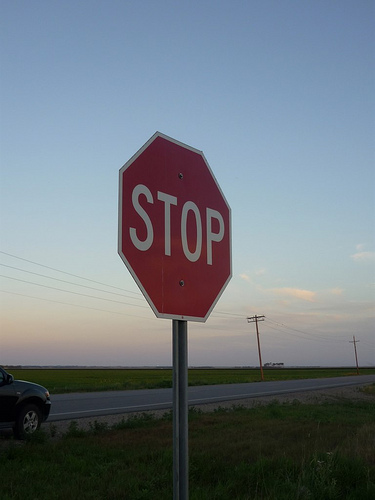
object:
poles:
[254, 315, 264, 381]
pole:
[171, 318, 189, 500]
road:
[209, 374, 371, 412]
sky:
[1, 3, 124, 284]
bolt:
[180, 280, 184, 286]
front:
[42, 385, 51, 421]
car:
[0, 362, 52, 439]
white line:
[118, 177, 122, 251]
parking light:
[45, 391, 50, 398]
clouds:
[13, 315, 169, 361]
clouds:
[325, 329, 371, 361]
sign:
[118, 132, 234, 323]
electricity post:
[246, 314, 264, 382]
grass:
[241, 400, 362, 500]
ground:
[68, 408, 363, 494]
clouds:
[264, 285, 316, 310]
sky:
[257, 2, 371, 299]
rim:
[24, 411, 38, 434]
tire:
[12, 404, 39, 439]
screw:
[179, 172, 182, 178]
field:
[3, 365, 375, 500]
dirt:
[75, 419, 167, 493]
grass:
[2, 432, 112, 497]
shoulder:
[0, 381, 373, 446]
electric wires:
[260, 323, 286, 334]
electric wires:
[0, 251, 104, 286]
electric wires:
[212, 310, 235, 316]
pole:
[353, 335, 359, 375]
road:
[21, 383, 203, 423]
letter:
[129, 185, 153, 252]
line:
[49, 377, 374, 417]